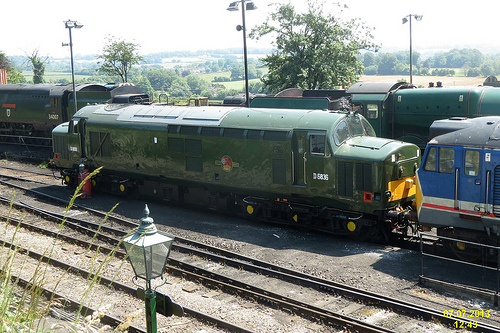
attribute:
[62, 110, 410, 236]
railroad car — dark, green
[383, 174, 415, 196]
stripe — yellow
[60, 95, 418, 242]
train — striped, green, parked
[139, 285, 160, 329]
lamppost — green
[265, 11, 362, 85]
leaves — green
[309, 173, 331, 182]
numbers — white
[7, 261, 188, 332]
railroad tracks — metal, empty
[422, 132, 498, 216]
train — blue, striped, parked, white, red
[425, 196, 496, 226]
stripe — red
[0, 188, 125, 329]
weeds — tall, green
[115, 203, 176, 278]
lamp — off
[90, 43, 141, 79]
tree — small, green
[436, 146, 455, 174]
widow — small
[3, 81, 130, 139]
train — parked, green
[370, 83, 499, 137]
train — parked, green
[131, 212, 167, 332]
street lamp — "green, green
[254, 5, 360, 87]
tree — green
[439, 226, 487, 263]
wheel — black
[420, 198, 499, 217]
line — red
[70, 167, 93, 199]
box — red